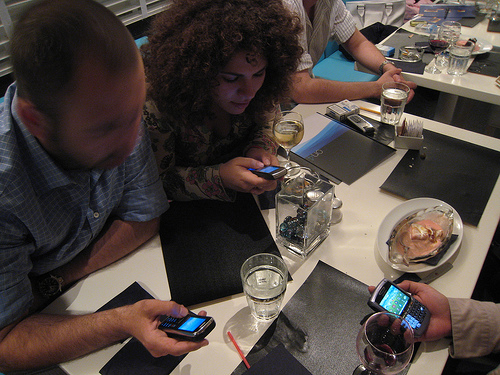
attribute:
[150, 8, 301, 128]
hair — curly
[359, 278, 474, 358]
phone — blackberry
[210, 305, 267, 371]
straw — red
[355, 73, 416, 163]
glass — of water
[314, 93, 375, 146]
package — white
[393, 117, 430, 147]
box — small 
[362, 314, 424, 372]
glass — Big 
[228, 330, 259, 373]
straw — red 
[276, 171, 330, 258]
glass — square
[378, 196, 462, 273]
plate — small, white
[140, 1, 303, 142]
hair — curly, brown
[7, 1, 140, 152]
hair — black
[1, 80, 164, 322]
shirt — plaid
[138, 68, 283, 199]
jacket — floral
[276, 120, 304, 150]
wine — white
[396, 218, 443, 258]
custard — pink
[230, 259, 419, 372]
mat — black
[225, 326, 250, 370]
straw — red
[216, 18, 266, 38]
hair — curly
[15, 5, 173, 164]
person — white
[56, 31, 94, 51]
hair — short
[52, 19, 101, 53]
hair — dark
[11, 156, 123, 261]
shirt — blue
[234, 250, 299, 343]
glass — clear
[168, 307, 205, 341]
phone — black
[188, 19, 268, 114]
woman — puffy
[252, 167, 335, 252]
container — glass, clear